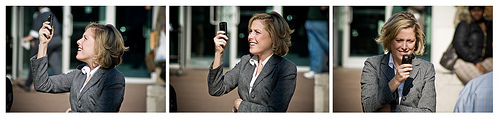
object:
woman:
[28, 21, 125, 113]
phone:
[41, 12, 53, 39]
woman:
[208, 11, 298, 112]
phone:
[217, 21, 229, 41]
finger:
[395, 63, 410, 69]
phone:
[401, 53, 412, 64]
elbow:
[33, 81, 60, 94]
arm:
[236, 63, 294, 111]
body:
[206, 30, 298, 113]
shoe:
[303, 69, 316, 79]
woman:
[359, 10, 440, 113]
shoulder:
[415, 58, 433, 67]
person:
[14, 6, 62, 92]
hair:
[85, 21, 130, 68]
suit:
[30, 56, 127, 112]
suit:
[207, 55, 296, 112]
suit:
[361, 53, 436, 112]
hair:
[246, 11, 296, 57]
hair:
[375, 12, 425, 60]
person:
[451, 6, 492, 84]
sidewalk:
[332, 68, 362, 113]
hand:
[38, 21, 54, 42]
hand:
[213, 31, 230, 52]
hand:
[395, 64, 414, 82]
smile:
[397, 49, 412, 52]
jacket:
[454, 17, 493, 65]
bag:
[441, 48, 459, 71]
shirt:
[81, 66, 100, 92]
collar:
[248, 55, 274, 65]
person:
[303, 6, 330, 79]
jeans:
[306, 21, 328, 73]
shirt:
[247, 55, 274, 94]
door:
[63, 6, 117, 73]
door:
[18, 6, 70, 78]